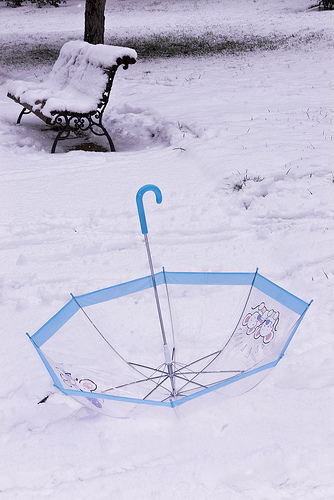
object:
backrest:
[44, 42, 137, 100]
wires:
[69, 293, 128, 369]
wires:
[222, 266, 260, 351]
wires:
[162, 266, 177, 370]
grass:
[172, 145, 186, 153]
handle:
[136, 184, 163, 234]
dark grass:
[234, 171, 249, 192]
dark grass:
[176, 119, 184, 131]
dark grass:
[302, 106, 313, 120]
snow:
[0, 159, 225, 263]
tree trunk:
[84, 0, 105, 42]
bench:
[5, 39, 137, 153]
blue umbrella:
[25, 183, 314, 421]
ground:
[0, 1, 332, 500]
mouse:
[242, 301, 269, 335]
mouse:
[254, 309, 280, 344]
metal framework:
[101, 354, 244, 399]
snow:
[0, 426, 334, 500]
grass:
[0, 27, 303, 69]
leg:
[49, 127, 64, 154]